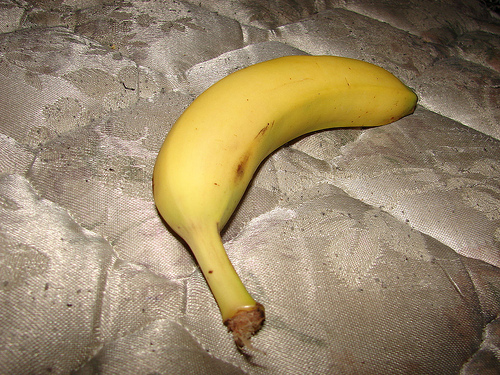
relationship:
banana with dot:
[151, 55, 418, 354] [230, 150, 251, 180]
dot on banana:
[221, 149, 266, 189] [151, 55, 418, 354]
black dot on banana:
[205, 270, 216, 277] [151, 55, 418, 354]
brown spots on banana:
[234, 149, 251, 183] [151, 55, 418, 354]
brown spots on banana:
[254, 123, 274, 139] [151, 55, 418, 354]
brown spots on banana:
[351, 108, 396, 128] [151, 55, 418, 354]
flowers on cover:
[70, 7, 166, 61] [7, 7, 499, 371]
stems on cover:
[79, 2, 154, 61] [7, 7, 499, 371]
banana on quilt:
[151, 55, 418, 354] [3, 7, 493, 374]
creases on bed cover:
[164, 51, 481, 318] [276, 100, 415, 276]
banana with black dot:
[114, 44, 330, 270] [230, 148, 255, 191]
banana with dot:
[151, 55, 418, 354] [232, 158, 253, 189]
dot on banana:
[205, 267, 215, 274] [151, 55, 418, 354]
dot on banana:
[211, 181, 221, 186] [151, 55, 418, 354]